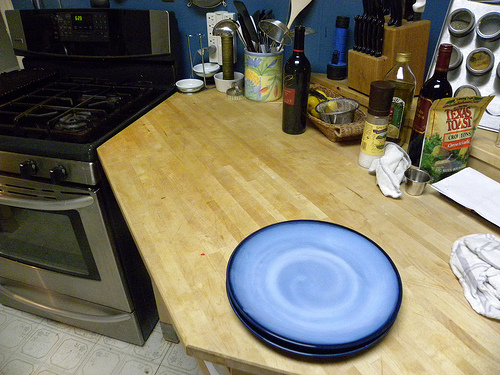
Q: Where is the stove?
A: Next to the counter.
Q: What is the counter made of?
A: Wood.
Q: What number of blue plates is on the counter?
A: Two.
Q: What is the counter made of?
A: Wood.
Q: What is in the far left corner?
A: A stove.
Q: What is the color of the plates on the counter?
A: Blue.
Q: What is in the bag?
A: Croutons.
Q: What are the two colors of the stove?
A: Black and silver.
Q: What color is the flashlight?
A: Blue and black.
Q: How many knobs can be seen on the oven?
A: Two.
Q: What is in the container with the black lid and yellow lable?
A: Salt.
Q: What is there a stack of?
A: Two blue plates.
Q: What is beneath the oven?
A: The floor.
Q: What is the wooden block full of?
A: Knives.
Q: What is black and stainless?
A: The kitchen stove.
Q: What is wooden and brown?
A: Counter top.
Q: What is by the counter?
A: Silver oven.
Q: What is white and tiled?
A: Floor.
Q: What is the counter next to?
A: A stove.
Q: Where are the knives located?
A: Wooden block.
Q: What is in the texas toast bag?
A: Croutons.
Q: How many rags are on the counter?
A: Two.